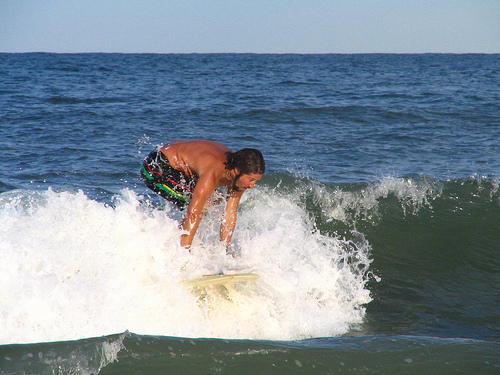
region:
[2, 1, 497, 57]
Clear and blue sky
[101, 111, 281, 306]
Man surfing on wave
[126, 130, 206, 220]
Black, red, yellow, and green swim trunks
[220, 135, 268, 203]
Long brown hair and beard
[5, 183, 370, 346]
White wave crashing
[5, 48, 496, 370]
Blue ocean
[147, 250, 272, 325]
White surfboard under man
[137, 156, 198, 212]
Stripes on man's swim trunks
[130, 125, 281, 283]
Surfer hunched over on surfboard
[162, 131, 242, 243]
Tanned summer skin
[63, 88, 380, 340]
person sufing on waves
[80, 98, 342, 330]
person sufing on ocean waves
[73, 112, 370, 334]
person sufing on nice waves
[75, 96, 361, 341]
person sufing on nice ocean waves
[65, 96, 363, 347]
person sufing on some waves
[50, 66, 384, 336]
person sufing on some nice waves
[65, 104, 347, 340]
person sufing on some beautiful waves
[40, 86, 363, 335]
person sufing on really attractive waves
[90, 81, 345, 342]
person sufing on very strong waves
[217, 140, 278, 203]
person with dark colored hair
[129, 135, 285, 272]
a man riding a surfboard.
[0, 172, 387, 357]
a foamy wave in the ocean.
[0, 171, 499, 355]
a wave in the ocean.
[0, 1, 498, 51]
a clear blue sky.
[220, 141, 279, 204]
a surfer with long hair.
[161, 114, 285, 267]
a surfer without a shirt.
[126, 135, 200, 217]
a surfer wearing swim trunks.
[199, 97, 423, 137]
a wave in the ocean.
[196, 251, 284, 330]
a surf board in a wave.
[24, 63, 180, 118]
a wave in the water.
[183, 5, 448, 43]
this is the sky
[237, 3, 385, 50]
the sky is blue in color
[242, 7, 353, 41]
the sky has some clouds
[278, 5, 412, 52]
the clouds are white in color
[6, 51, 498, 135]
this is an ocean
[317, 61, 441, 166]
this is the water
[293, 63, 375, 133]
the water is unsettled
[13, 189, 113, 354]
this is raised water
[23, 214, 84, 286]
the water is white in color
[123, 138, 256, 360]
the man is surfing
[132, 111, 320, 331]
man on a surfboard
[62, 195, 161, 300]
white waves in water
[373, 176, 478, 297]
wave forming in water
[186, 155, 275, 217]
long hair on man's head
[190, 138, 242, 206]
dark skin of man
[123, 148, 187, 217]
shorts of the man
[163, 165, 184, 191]
red stripe on shorts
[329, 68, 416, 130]
calm ocean in background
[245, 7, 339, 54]
blue sky in background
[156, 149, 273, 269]
man bent over in water